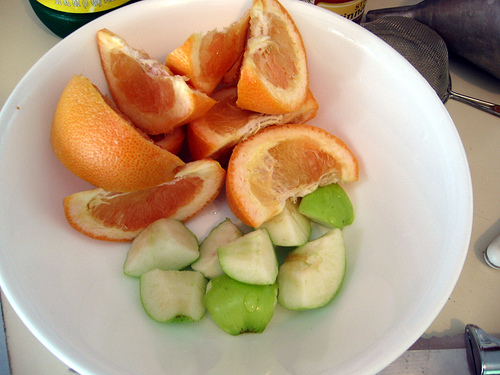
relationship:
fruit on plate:
[68, 32, 353, 324] [6, 4, 465, 371]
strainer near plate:
[358, 10, 499, 112] [6, 4, 465, 371]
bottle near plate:
[302, 0, 371, 35] [6, 4, 465, 371]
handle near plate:
[475, 221, 498, 278] [6, 4, 465, 371]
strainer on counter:
[358, 10, 499, 112] [1, 3, 498, 335]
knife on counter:
[407, 334, 497, 375] [1, 3, 498, 335]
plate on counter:
[6, 4, 465, 371] [1, 3, 498, 335]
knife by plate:
[407, 334, 497, 375] [6, 4, 465, 371]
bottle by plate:
[302, 0, 371, 35] [6, 4, 465, 371]